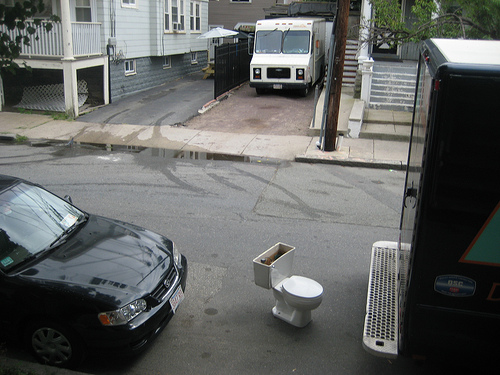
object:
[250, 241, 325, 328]
toilet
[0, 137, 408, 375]
street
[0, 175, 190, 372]
car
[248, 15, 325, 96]
truck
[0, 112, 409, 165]
sidewalk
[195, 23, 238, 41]
umbrella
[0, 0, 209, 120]
house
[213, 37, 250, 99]
railings